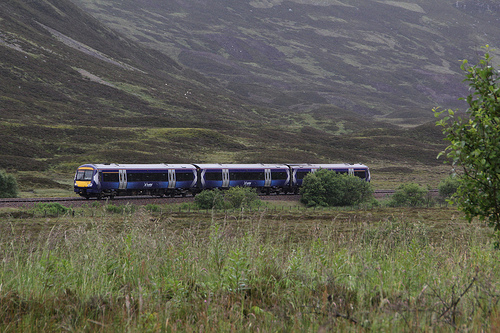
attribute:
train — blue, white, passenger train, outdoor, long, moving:
[73, 163, 371, 199]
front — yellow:
[71, 165, 99, 199]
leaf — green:
[447, 106, 463, 119]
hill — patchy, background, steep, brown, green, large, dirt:
[2, 1, 496, 184]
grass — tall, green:
[2, 201, 499, 331]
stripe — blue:
[100, 178, 304, 191]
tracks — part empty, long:
[0, 190, 397, 204]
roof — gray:
[82, 160, 367, 171]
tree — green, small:
[428, 42, 497, 237]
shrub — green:
[299, 169, 375, 211]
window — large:
[73, 170, 96, 183]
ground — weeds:
[5, 195, 499, 332]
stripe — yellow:
[77, 166, 95, 172]